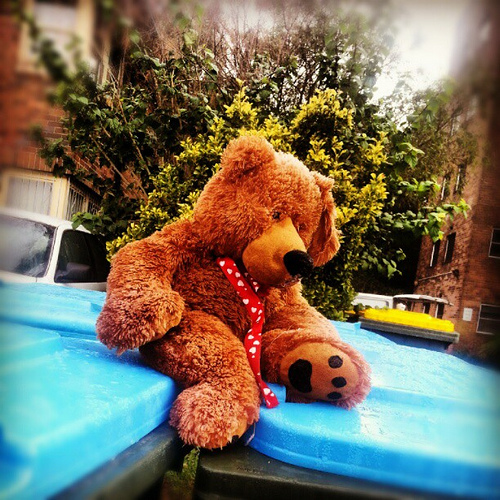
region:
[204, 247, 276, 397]
the ribbon is red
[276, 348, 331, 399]
this is a foot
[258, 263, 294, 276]
this is a nose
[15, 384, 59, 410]
this is a can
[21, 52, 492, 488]
teddy bear on trash cans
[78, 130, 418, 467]
large brown stuffed bear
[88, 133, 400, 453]
bear wearing a red ribbon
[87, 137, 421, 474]
bear wearing a red ribbon with white hearts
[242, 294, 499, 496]
blue lids on a garbage can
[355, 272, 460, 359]
trash can with yellow lid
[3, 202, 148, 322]
a white vehicle with tinted windows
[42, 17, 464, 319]
over grown green shrubs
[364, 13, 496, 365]
brick apartment buildings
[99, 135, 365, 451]
brown plush stuffed bear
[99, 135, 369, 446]
stuffed bear on bench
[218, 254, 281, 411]
red and white ribbon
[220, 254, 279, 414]
red ribbon on bear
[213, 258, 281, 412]
red ribbon with white hearts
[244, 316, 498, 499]
blue plastic bench seat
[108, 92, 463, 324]
tree with green leaves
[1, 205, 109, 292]
white car in lot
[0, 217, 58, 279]
wind shield on car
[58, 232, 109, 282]
side window on car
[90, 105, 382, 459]
A teddy bear on blue tables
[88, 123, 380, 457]
A teddy bear on blue tables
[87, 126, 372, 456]
A teddy bear on blue tables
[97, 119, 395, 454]
A teddy bear on blue tables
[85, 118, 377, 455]
A teddy bear on blue tables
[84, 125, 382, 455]
A teddy bear on blue tables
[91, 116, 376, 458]
A teddy bear on blue tables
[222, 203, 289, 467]
the neck colar is white and red in color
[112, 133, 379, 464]
a brown teddy bear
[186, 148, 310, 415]
a bear with a red tie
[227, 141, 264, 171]
ear of the bear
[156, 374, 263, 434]
foot of the bear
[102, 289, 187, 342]
paw of the bear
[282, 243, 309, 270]
nose of the bear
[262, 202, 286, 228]
eye of the bear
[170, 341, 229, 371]
the fur is brown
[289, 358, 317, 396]
footprint of the bear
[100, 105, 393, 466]
A toy stuffed animal.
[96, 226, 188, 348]
A limb on a stuffed animal.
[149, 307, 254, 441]
A limb on a stuffed animal.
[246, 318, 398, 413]
A limb on a stuffed animal.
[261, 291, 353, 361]
A limb on a stuffed animal.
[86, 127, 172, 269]
A shrub in the ground.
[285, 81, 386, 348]
A shrub in the ground.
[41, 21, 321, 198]
A shrub in the ground.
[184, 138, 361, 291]
head of a bear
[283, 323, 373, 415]
foot of the bear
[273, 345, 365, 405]
bottom of the foot